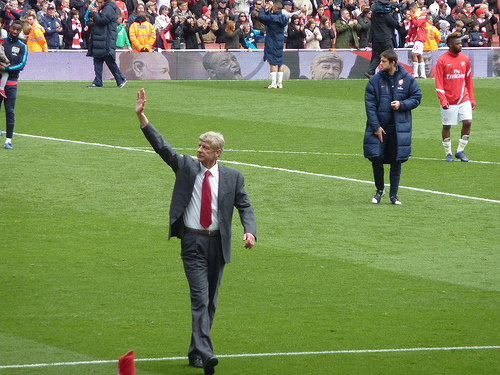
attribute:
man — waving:
[131, 86, 263, 368]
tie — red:
[203, 175, 212, 231]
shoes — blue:
[447, 153, 470, 164]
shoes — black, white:
[373, 187, 400, 205]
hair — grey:
[201, 130, 223, 153]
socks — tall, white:
[443, 134, 469, 157]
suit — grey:
[151, 122, 258, 360]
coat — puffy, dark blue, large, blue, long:
[360, 73, 422, 161]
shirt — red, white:
[433, 56, 473, 107]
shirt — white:
[185, 159, 220, 231]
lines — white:
[5, 129, 496, 203]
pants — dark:
[367, 125, 403, 197]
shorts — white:
[444, 97, 473, 128]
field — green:
[9, 77, 500, 373]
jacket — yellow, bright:
[130, 26, 158, 52]